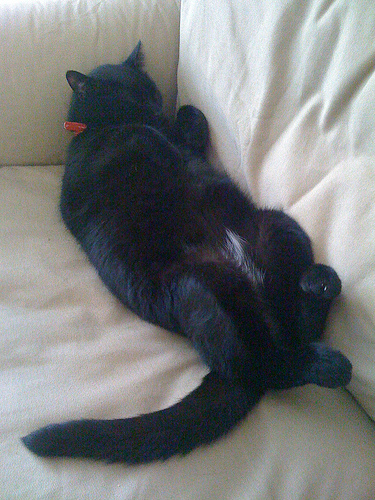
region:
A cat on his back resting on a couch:
[12, 36, 361, 467]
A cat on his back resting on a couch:
[19, 37, 360, 470]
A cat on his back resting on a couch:
[14, 36, 357, 469]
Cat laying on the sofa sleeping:
[45, 30, 221, 191]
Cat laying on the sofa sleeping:
[22, 32, 282, 260]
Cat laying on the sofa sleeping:
[57, 165, 312, 310]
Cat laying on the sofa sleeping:
[37, 26, 345, 285]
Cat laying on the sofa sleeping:
[44, 47, 276, 201]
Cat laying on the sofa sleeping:
[51, 39, 307, 469]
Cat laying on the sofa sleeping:
[57, 43, 310, 284]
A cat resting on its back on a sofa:
[15, 35, 357, 470]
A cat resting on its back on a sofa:
[11, 36, 354, 472]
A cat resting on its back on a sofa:
[11, 33, 360, 472]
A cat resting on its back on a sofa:
[17, 38, 362, 469]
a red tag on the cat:
[56, 111, 91, 130]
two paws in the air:
[290, 261, 353, 393]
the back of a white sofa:
[171, 11, 373, 375]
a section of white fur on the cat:
[189, 198, 278, 307]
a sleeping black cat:
[51, 39, 356, 403]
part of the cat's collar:
[58, 118, 86, 132]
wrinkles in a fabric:
[218, 1, 373, 187]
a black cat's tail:
[17, 372, 265, 468]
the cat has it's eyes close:
[62, 43, 169, 129]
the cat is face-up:
[15, 38, 366, 485]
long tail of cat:
[17, 373, 258, 473]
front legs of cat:
[86, 100, 222, 196]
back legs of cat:
[193, 217, 343, 392]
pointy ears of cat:
[53, 36, 154, 99]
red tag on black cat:
[56, 33, 174, 160]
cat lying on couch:
[6, 9, 367, 494]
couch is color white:
[2, 10, 373, 495]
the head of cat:
[46, 33, 183, 153]